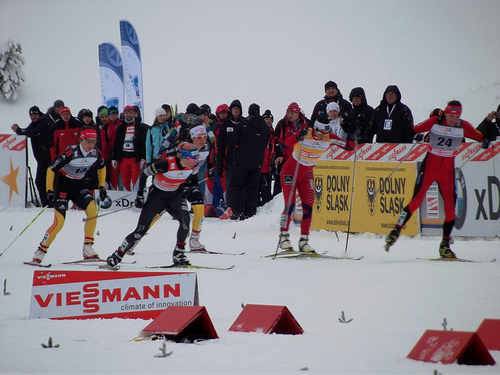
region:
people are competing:
[6, 9, 493, 374]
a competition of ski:
[3, 60, 493, 370]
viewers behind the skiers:
[1, 75, 488, 285]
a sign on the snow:
[24, 262, 208, 329]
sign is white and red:
[26, 262, 201, 327]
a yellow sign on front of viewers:
[324, 71, 424, 246]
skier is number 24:
[390, 90, 487, 265]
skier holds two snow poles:
[265, 111, 370, 266]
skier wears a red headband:
[37, 115, 117, 202]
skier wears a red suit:
[381, 95, 488, 266]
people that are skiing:
[69, 63, 486, 351]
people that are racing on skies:
[73, 87, 493, 309]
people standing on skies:
[76, 110, 499, 329]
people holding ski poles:
[42, 79, 488, 308]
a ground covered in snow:
[68, 167, 363, 363]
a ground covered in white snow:
[50, 194, 344, 371]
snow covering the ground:
[33, 181, 353, 361]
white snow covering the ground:
[116, 185, 467, 374]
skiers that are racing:
[11, 35, 479, 305]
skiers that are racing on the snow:
[48, 91, 488, 360]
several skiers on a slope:
[44, 123, 446, 292]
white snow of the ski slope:
[318, 272, 434, 297]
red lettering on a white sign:
[48, 281, 168, 304]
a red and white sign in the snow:
[27, 263, 204, 325]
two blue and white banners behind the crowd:
[88, 14, 153, 126]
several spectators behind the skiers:
[51, 90, 394, 149]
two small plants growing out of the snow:
[33, 325, 173, 367]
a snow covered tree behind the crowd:
[0, 29, 40, 99]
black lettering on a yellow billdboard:
[313, 166, 406, 215]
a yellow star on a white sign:
[0, 155, 30, 196]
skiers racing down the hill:
[40, 102, 494, 268]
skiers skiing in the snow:
[26, 100, 499, 270]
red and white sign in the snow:
[28, 263, 199, 322]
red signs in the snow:
[135, 303, 499, 363]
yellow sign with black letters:
[299, 158, 419, 234]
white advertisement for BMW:
[439, 161, 499, 238]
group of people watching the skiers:
[12, 85, 498, 219]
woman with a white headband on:
[166, 122, 216, 253]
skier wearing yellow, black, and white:
[23, 125, 131, 268]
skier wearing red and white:
[382, 100, 494, 257]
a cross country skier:
[381, 100, 496, 264]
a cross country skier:
[263, 113, 363, 260]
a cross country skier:
[91, 144, 234, 269]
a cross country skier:
[1, 128, 137, 267]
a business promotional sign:
[31, 270, 196, 320]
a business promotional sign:
[354, 159, 416, 235]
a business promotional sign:
[310, 161, 353, 231]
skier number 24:
[434, 133, 454, 149]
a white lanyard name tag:
[383, 101, 395, 131]